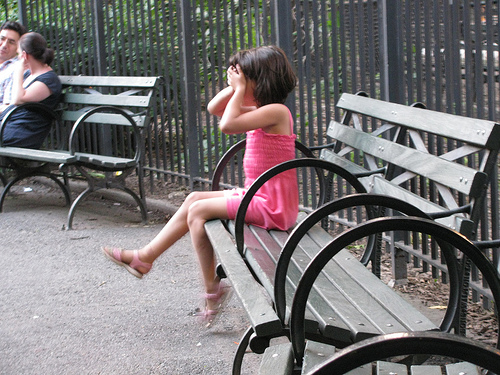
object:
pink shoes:
[98, 243, 157, 279]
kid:
[100, 42, 301, 327]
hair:
[20, 32, 56, 63]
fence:
[182, 0, 389, 268]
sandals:
[198, 281, 237, 329]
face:
[238, 63, 258, 107]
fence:
[99, 0, 181, 183]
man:
[1, 20, 23, 113]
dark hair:
[234, 43, 295, 110]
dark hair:
[21, 32, 54, 63]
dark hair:
[1, 21, 23, 35]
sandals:
[100, 243, 156, 281]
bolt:
[458, 176, 464, 183]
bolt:
[476, 129, 482, 136]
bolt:
[377, 146, 381, 151]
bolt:
[391, 110, 395, 114]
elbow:
[219, 117, 237, 134]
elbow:
[203, 99, 221, 116]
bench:
[0, 73, 161, 232]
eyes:
[9, 41, 14, 45]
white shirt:
[0, 55, 23, 114]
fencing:
[383, 2, 497, 308]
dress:
[227, 112, 297, 230]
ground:
[0, 261, 490, 375]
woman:
[0, 30, 61, 157]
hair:
[227, 47, 294, 106]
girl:
[99, 33, 305, 331]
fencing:
[26, 0, 100, 185]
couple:
[0, 21, 61, 150]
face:
[0, 29, 16, 61]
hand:
[227, 64, 247, 90]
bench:
[199, 92, 500, 375]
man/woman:
[0, 20, 61, 152]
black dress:
[1, 68, 62, 148]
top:
[4, 66, 65, 150]